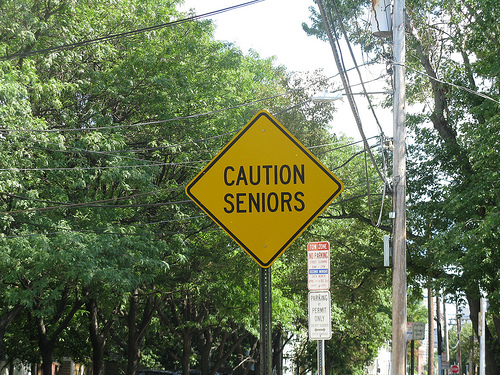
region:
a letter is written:
[222, 163, 236, 187]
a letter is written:
[233, 162, 248, 187]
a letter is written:
[243, 160, 265, 191]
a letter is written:
[260, 157, 273, 184]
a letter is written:
[271, 160, 281, 187]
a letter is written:
[278, 163, 291, 186]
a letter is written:
[291, 157, 307, 185]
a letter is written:
[219, 187, 234, 218]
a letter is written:
[232, 190, 247, 215]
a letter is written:
[246, 188, 262, 210]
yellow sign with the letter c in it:
[180, 108, 352, 275]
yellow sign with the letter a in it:
[180, 91, 340, 270]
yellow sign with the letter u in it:
[180, 93, 359, 278]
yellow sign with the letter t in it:
[180, 102, 344, 289]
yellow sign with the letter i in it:
[178, 95, 362, 267]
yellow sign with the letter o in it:
[173, 103, 371, 274]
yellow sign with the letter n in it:
[161, 108, 358, 249]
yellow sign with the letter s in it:
[167, 84, 377, 282]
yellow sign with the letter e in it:
[186, 111, 361, 296]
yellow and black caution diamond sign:
[188, 108, 334, 263]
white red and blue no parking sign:
[307, 240, 332, 292]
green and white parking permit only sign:
[306, 291, 334, 337]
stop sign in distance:
[450, 363, 462, 373]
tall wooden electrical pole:
[377, 1, 414, 373]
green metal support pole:
[255, 264, 276, 374]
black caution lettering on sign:
[222, 161, 307, 185]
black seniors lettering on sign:
[223, 191, 307, 212]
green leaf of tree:
[30, 187, 40, 195]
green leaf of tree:
[158, 256, 169, 276]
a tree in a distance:
[103, 211, 153, 371]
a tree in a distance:
[73, 237, 128, 374]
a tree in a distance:
[24, 237, 82, 372]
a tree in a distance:
[0, 200, 42, 366]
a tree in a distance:
[166, 232, 201, 369]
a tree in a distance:
[207, 213, 261, 372]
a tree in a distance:
[331, 220, 379, 369]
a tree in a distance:
[287, 248, 309, 370]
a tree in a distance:
[402, 33, 462, 192]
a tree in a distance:
[448, 90, 498, 284]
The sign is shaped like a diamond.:
[197, 112, 327, 267]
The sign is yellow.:
[188, 108, 361, 248]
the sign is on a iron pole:
[250, 264, 285, 366]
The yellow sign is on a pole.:
[195, 125, 300, 365]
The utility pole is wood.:
[372, 53, 422, 373]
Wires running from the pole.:
[35, 62, 388, 243]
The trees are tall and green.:
[35, 37, 242, 344]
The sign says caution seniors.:
[216, 120, 334, 272]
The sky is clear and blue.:
[250, 0, 370, 81]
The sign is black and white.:
[287, 281, 345, 357]